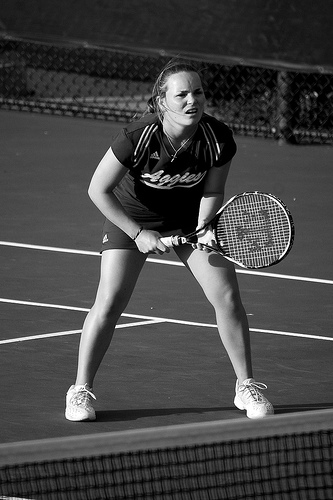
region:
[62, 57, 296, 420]
a woman playing tennis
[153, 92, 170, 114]
the ear of a woman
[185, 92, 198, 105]
the nose of a woman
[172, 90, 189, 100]
the eye of a woman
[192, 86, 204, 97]
the eye of a woman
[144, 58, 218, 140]
the head of a woman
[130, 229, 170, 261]
the hand of a woman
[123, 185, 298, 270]
a tennis racket in the hands of a woman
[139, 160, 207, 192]
writing on the front of a shirt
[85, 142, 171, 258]
the arm of a woman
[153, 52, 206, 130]
a womans round face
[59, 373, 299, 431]
woman has on white sneakers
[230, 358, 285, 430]
womans shoe is tied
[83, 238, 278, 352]
womans legs are showing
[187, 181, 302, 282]
a black and white rachet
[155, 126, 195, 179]
woman is wearing necklace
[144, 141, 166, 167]
a sports symbol on shirt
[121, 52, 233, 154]
the head of a woman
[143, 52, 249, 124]
the face of a woman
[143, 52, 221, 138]
the hair of a woman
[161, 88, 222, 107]
the eyes of a woman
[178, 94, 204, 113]
the nose of a woman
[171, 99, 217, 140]
the lips of a woman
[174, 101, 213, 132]
the teeth of a woman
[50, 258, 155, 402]
the leg of a woman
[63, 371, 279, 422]
Woman is wearing shoes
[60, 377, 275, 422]
Woman wearing white shoes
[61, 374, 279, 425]
Woman is wearing white shoes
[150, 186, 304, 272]
Woman holding a racket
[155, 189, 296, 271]
Woman is holding a racket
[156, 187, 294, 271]
Woman holding a tennis racket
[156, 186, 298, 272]
Woman is holding a tennis racket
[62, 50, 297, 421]
Woman playing tennis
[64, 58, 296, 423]
Woman is playing tennis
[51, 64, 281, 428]
this is a lady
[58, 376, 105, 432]
this is a shoe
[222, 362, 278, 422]
this is a shoe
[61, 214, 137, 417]
this is a leg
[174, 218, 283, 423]
this is a leg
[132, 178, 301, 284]
this is a racket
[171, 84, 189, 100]
this is an eye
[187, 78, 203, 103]
this is an eye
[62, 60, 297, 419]
woman is holding a tennis racket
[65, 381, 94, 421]
tennis shoe is white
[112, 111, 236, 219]
Aggies written on shirt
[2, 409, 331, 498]
white trim on tennis net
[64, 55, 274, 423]
woman is wearing dark shorts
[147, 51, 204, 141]
hair is dark and pulled back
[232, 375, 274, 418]
white laces on white tennis shoe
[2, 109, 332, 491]
white lines on tennis court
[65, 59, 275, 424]
woman is wearing a necklace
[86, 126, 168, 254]
band on arm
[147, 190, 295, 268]
Racket in a tennis player's hand.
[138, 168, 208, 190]
Team name in white letters on a shirt.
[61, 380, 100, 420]
Players right foot on the ground.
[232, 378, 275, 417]
Player's left foot with the heel raised.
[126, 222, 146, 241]
Bracelet on a tennis player's wrist.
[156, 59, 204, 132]
Head of a girl with a tennis racket.